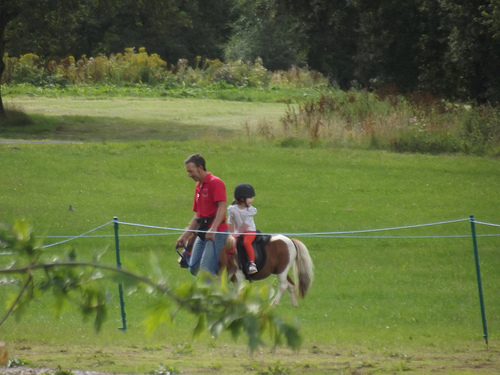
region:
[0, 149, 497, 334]
green grass of field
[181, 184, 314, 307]
girl sitting on pony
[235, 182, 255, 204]
helmet on girl's head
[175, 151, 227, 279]
man walking with reigns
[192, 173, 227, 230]
red shirt with short sleeves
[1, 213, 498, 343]
rope suspended from poles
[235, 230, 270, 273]
saddle on top of pony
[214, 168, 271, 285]
this is a young girl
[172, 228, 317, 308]
this is a horse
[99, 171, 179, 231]
the grass on the ground is lush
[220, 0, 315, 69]
this is a tree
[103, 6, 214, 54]
this is a tree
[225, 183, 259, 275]
little girl looking backwards while riding a pony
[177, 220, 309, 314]
small brown an white pony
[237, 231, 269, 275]
black riding saddle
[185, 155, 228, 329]
man leading pony girl is riding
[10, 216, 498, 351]
one rope fence marking riding trail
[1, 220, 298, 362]
tree branch extending into photos foreground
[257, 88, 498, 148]
area of tall grasses and wild flowers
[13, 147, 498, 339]
area of mown lawn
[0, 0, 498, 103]
area of dense forrest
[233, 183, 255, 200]
child sized black riding helmet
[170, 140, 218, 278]
man wearing red shirt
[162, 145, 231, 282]
man wearing blue jeans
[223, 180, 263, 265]
girl wearing white shirt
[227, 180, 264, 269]
girl wearing orange leggings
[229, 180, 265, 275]
girl wearing black helmet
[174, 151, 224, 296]
man leading the pony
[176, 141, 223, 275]
man wearing black fannie pack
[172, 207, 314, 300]
brown and white pony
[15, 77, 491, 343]
grass covering the ground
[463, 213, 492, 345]
a long green pole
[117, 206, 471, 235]
a long gray rope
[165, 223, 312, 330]
a small brown and white horse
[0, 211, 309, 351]
part of a tree branch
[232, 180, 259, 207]
a black helmet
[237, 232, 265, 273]
part of a black horse saddle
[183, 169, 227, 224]
a man's red shirt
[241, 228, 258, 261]
the leg of a girl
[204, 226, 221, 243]
the hand of a man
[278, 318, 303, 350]
green leaf on branch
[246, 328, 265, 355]
green leaf on branch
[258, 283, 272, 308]
green leaf on branch